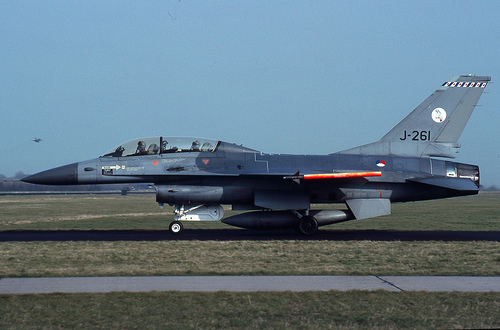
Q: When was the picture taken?
A: Daytime.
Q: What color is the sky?
A: Blue.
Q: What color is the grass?
A: Green.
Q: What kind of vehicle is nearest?
A: A plane.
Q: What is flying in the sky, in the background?
A: A plane.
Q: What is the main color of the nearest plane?
A: Gray.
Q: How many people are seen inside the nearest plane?
A: Two.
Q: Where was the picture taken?
A: Airfield.